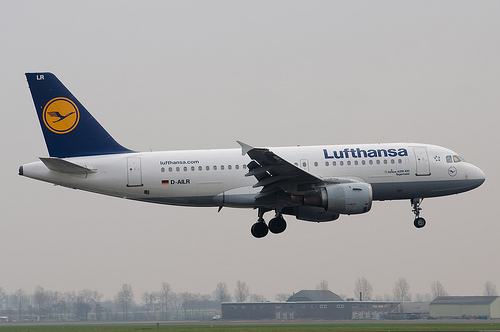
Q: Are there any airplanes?
A: Yes, there is an airplane.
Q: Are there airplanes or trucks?
A: Yes, there is an airplane.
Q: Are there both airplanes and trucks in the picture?
A: No, there is an airplane but no trucks.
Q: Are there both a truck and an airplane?
A: No, there is an airplane but no trucks.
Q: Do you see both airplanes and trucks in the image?
A: No, there is an airplane but no trucks.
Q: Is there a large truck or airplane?
A: Yes, there is a large airplane.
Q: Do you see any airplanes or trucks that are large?
A: Yes, the airplane is large.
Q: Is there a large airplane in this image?
A: Yes, there is a large airplane.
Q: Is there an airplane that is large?
A: Yes, there is an airplane that is large.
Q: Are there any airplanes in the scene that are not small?
A: Yes, there is a large airplane.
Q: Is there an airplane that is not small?
A: Yes, there is a large airplane.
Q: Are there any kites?
A: No, there are no kites.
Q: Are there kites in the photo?
A: No, there are no kites.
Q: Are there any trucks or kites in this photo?
A: No, there are no kites or trucks.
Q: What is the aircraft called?
A: The aircraft is an airplane.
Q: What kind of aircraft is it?
A: The aircraft is an airplane.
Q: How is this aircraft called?
A: This is an airplane.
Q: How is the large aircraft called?
A: The aircraft is an airplane.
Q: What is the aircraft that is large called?
A: The aircraft is an airplane.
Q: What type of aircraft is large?
A: The aircraft is an airplane.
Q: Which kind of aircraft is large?
A: The aircraft is an airplane.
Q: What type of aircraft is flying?
A: The aircraft is an airplane.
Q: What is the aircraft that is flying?
A: The aircraft is an airplane.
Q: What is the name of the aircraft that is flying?
A: The aircraft is an airplane.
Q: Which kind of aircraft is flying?
A: The aircraft is an airplane.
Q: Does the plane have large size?
A: Yes, the plane is large.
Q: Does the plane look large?
A: Yes, the plane is large.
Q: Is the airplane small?
A: No, the airplane is large.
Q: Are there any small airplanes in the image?
A: No, there is an airplane but it is large.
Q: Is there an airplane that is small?
A: No, there is an airplane but it is large.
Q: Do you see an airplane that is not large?
A: No, there is an airplane but it is large.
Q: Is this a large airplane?
A: Yes, this is a large airplane.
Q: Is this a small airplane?
A: No, this is a large airplane.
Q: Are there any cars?
A: No, there are no cars.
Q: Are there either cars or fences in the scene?
A: No, there are no cars or fences.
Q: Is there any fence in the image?
A: No, there are no fences.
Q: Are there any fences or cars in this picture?
A: No, there are no fences or cars.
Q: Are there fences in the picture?
A: No, there are no fences.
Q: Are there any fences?
A: No, there are no fences.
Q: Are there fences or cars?
A: No, there are no fences or cars.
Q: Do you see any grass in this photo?
A: Yes, there is grass.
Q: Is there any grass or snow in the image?
A: Yes, there is grass.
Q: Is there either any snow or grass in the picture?
A: Yes, there is grass.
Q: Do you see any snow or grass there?
A: Yes, there is grass.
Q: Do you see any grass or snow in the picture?
A: Yes, there is grass.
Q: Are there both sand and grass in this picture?
A: No, there is grass but no sand.